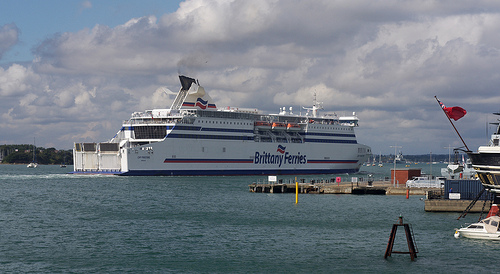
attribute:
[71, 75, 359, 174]
ship — red, blue, white,, large, white, & blue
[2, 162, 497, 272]
water — calm, blue, rippled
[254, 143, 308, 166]
logo — blue, red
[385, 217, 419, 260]
buoy — rusted, old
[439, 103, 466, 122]
flag — red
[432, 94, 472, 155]
pole — black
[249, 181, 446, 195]
pier — brown, wooden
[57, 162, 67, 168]
boat — small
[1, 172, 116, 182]
water — white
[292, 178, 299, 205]
pole — yellow, long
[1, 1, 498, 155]
sky — blue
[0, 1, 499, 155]
clouds — thick, gray, billowing, white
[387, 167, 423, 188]
building — brick, small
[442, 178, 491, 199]
container — blue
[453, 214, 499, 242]
boat — white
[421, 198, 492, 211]
concrete — gray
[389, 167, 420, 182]
container — red